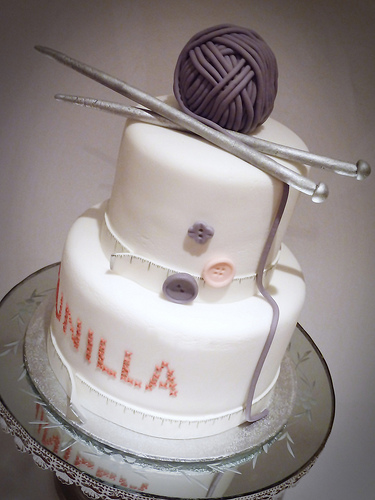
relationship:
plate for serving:
[15, 256, 363, 484] [291, 416, 355, 480]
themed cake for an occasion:
[66, 174, 281, 422] [61, 387, 161, 415]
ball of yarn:
[171, 19, 280, 134] [199, 108, 251, 127]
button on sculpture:
[161, 273, 197, 305] [33, 101, 318, 352]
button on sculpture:
[203, 256, 237, 289] [26, 105, 283, 407]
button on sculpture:
[180, 220, 218, 258] [70, 119, 290, 341]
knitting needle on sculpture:
[68, 62, 359, 210] [64, 245, 289, 444]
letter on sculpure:
[150, 353, 181, 412] [41, 146, 319, 462]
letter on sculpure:
[114, 342, 141, 402] [17, 121, 334, 498]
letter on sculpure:
[90, 341, 111, 386] [28, 122, 305, 450]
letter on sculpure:
[71, 317, 96, 372] [28, 115, 328, 458]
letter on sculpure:
[59, 295, 87, 361] [33, 90, 363, 422]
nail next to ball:
[28, 41, 329, 204] [181, 22, 275, 135]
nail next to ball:
[37, 49, 312, 242] [165, 13, 300, 161]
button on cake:
[164, 206, 241, 311] [56, 113, 338, 473]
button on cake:
[188, 241, 253, 301] [50, 127, 322, 457]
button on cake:
[184, 220, 215, 249] [50, 127, 322, 457]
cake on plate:
[37, 116, 362, 410] [8, 260, 341, 497]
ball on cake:
[180, 26, 289, 141] [32, 198, 322, 485]